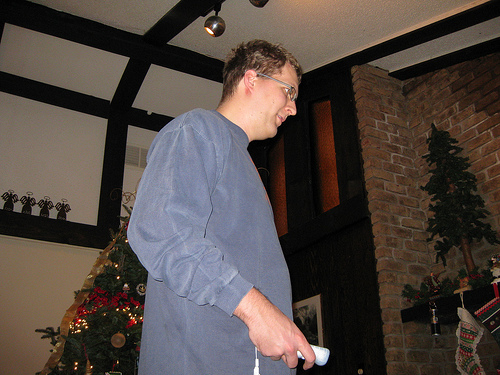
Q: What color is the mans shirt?
A: Blue.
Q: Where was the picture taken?
A: House.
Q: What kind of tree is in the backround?
A: Christmas.